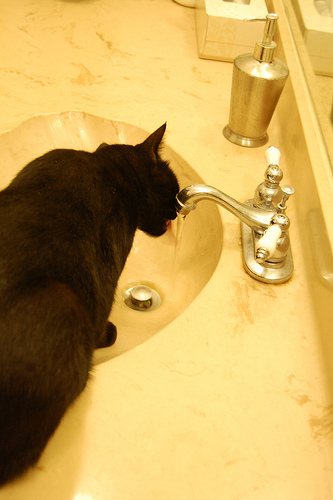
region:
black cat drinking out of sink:
[56, 118, 300, 295]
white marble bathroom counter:
[28, 13, 128, 101]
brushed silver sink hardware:
[173, 140, 300, 294]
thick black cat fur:
[44, 173, 100, 244]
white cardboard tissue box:
[187, 0, 227, 66]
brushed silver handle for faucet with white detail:
[261, 143, 284, 186]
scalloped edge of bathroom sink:
[9, 97, 106, 134]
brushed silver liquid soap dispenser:
[214, 6, 292, 148]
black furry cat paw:
[86, 304, 121, 350]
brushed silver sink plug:
[120, 279, 163, 315]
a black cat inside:
[18, 88, 267, 403]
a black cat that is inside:
[41, 97, 326, 338]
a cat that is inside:
[15, 90, 217, 379]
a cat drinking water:
[21, 86, 320, 257]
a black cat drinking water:
[42, 95, 269, 287]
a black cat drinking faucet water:
[93, 108, 235, 333]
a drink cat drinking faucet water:
[78, 133, 289, 287]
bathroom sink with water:
[121, 106, 328, 307]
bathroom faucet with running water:
[115, 131, 320, 277]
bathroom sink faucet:
[86, 80, 290, 309]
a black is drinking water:
[0, 111, 191, 491]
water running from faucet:
[167, 194, 201, 274]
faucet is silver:
[165, 177, 260, 241]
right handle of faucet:
[242, 212, 299, 274]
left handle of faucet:
[254, 135, 290, 187]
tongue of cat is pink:
[156, 209, 180, 246]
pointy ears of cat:
[87, 107, 174, 161]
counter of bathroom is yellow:
[0, 30, 327, 496]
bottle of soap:
[215, 29, 292, 152]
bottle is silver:
[213, 35, 294, 156]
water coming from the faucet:
[170, 211, 186, 290]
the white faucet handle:
[256, 220, 286, 268]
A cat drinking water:
[2, 110, 187, 439]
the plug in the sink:
[127, 281, 155, 314]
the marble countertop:
[206, 295, 320, 462]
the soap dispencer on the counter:
[216, 8, 289, 152]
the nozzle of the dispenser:
[245, 8, 278, 44]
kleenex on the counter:
[197, 2, 262, 61]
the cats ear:
[133, 116, 170, 170]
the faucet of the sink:
[173, 174, 269, 233]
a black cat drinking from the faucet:
[12, 72, 266, 356]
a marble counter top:
[122, 366, 253, 460]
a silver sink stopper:
[124, 285, 156, 319]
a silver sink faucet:
[197, 141, 294, 281]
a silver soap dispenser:
[234, 9, 285, 150]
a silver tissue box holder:
[184, 2, 262, 63]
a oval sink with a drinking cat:
[25, 92, 227, 341]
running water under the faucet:
[173, 203, 190, 291]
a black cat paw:
[95, 313, 121, 356]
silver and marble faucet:
[256, 212, 295, 266]